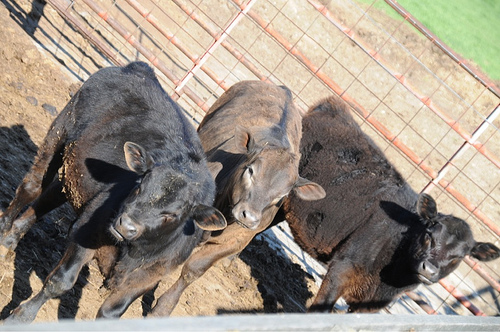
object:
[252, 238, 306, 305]
shadow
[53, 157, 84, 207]
mud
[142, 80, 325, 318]
cow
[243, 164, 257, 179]
eye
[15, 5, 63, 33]
shadow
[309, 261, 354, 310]
leg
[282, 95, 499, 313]
cow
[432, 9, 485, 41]
grass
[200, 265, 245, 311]
ground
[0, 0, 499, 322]
cage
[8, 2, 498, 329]
fence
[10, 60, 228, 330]
cow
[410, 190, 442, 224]
ear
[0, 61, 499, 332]
cow area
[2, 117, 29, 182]
shadow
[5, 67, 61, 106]
ground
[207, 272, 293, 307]
dirt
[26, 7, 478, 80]
rail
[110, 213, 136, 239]
nose